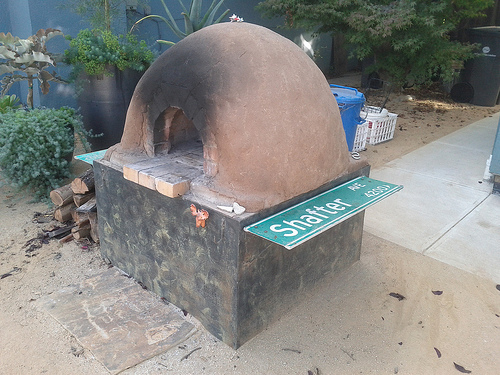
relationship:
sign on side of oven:
[243, 176, 403, 253] [101, 20, 369, 213]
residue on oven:
[155, 67, 204, 104] [101, 20, 369, 213]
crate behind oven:
[350, 113, 370, 151] [91, 20, 369, 348]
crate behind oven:
[361, 102, 398, 144] [91, 20, 369, 348]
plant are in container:
[62, 17, 159, 84] [76, 63, 157, 155]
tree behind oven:
[265, 4, 493, 88] [85, 20, 360, 207]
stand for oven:
[83, 148, 381, 359] [91, 20, 371, 348]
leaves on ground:
[384, 279, 471, 372] [381, 157, 498, 349]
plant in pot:
[62, 22, 159, 79] [79, 72, 147, 157]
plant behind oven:
[128, 0, 249, 57] [101, 20, 369, 213]